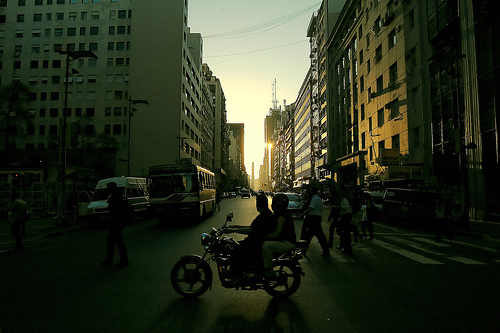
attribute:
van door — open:
[71, 192, 96, 218]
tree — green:
[1, 75, 42, 142]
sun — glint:
[244, 143, 271, 155]